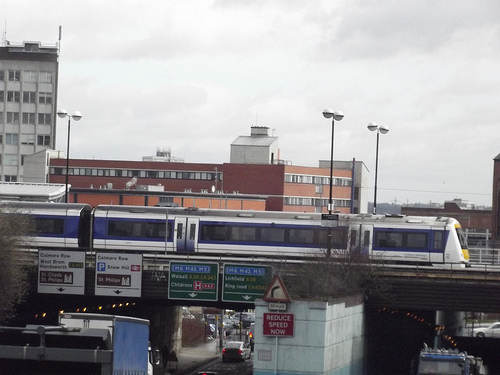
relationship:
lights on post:
[322, 106, 345, 122] [324, 102, 341, 211]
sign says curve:
[259, 309, 300, 341] [266, 275, 299, 308]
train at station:
[197, 206, 348, 258] [1, 176, 81, 215]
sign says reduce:
[259, 309, 300, 341] [266, 312, 292, 322]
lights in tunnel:
[96, 302, 134, 309] [38, 297, 255, 344]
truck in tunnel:
[414, 338, 465, 374] [391, 303, 473, 371]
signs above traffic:
[162, 256, 223, 305] [34, 310, 250, 366]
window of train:
[256, 221, 289, 244] [197, 206, 348, 258]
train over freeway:
[197, 206, 348, 258] [191, 311, 244, 374]